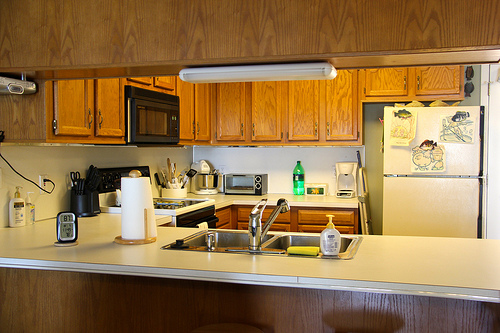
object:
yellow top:
[326, 214, 336, 229]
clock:
[56, 211, 79, 244]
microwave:
[124, 85, 182, 144]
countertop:
[187, 192, 359, 210]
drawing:
[390, 109, 418, 147]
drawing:
[411, 139, 446, 172]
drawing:
[438, 110, 477, 144]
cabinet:
[124, 75, 177, 96]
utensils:
[154, 158, 199, 190]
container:
[161, 187, 187, 198]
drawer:
[237, 208, 290, 224]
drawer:
[297, 209, 355, 226]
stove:
[96, 191, 219, 229]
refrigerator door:
[383, 105, 481, 175]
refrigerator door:
[382, 176, 479, 237]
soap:
[319, 214, 341, 257]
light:
[178, 62, 338, 84]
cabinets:
[285, 64, 466, 147]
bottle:
[8, 186, 26, 228]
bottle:
[24, 192, 36, 225]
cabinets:
[178, 79, 286, 146]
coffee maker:
[335, 161, 360, 200]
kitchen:
[0, 0, 499, 333]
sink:
[159, 229, 364, 261]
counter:
[0, 222, 498, 330]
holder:
[112, 168, 156, 246]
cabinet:
[177, 69, 363, 146]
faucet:
[224, 198, 291, 255]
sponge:
[287, 246, 319, 257]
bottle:
[292, 160, 305, 195]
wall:
[192, 146, 366, 194]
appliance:
[222, 173, 268, 196]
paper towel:
[120, 176, 158, 240]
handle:
[326, 121, 330, 136]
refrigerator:
[382, 105, 480, 239]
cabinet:
[0, 0, 499, 81]